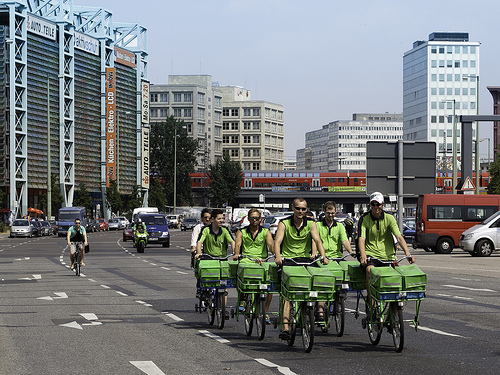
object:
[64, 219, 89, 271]
person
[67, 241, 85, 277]
bicycle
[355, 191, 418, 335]
man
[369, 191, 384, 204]
cap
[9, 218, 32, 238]
vehicle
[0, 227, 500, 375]
street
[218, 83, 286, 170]
building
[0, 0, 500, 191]
background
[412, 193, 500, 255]
van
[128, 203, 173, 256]
shirt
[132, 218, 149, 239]
man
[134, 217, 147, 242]
motorcycle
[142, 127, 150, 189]
sign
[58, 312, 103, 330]
arrow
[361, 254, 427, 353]
bicycle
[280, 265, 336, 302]
basket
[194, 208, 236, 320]
men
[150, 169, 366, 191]
train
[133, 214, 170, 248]
car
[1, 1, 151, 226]
building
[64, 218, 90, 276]
alone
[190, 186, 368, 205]
bridge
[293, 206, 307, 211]
sunglasses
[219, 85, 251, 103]
mast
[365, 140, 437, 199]
back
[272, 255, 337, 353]
bicycle